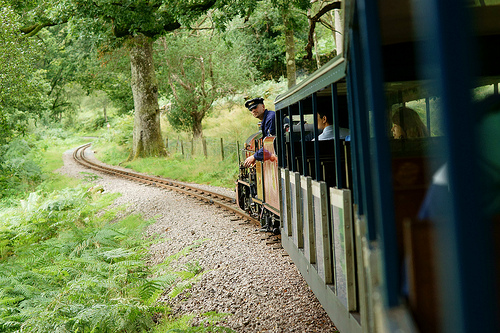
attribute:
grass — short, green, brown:
[20, 296, 55, 328]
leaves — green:
[106, 2, 196, 35]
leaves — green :
[39, 210, 145, 320]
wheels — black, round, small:
[239, 180, 279, 234]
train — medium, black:
[244, 0, 484, 326]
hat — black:
[246, 97, 260, 108]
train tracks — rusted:
[126, 168, 205, 200]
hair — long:
[394, 101, 431, 140]